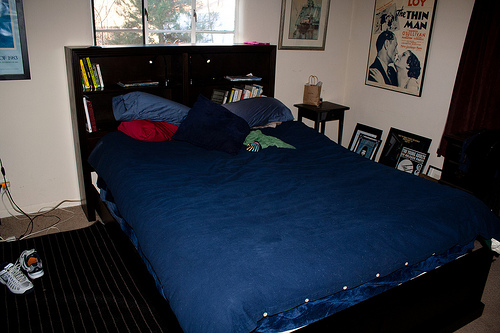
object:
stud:
[260, 310, 272, 320]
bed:
[103, 32, 498, 318]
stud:
[301, 294, 313, 308]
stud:
[339, 283, 352, 293]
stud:
[373, 268, 383, 281]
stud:
[399, 257, 416, 271]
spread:
[89, 106, 497, 312]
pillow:
[112, 120, 182, 141]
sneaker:
[0, 264, 36, 298]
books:
[113, 79, 162, 87]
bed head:
[58, 33, 285, 127]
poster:
[363, 0, 423, 97]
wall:
[281, 2, 453, 132]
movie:
[402, 9, 435, 32]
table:
[297, 99, 352, 143]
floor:
[38, 278, 150, 333]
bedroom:
[2, 4, 499, 332]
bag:
[303, 77, 323, 107]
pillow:
[110, 92, 191, 123]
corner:
[292, 103, 357, 126]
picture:
[277, 0, 326, 47]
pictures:
[0, 0, 31, 84]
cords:
[45, 196, 81, 211]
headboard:
[56, 37, 285, 99]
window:
[89, 2, 141, 33]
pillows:
[179, 103, 244, 154]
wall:
[22, 4, 280, 47]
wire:
[5, 178, 18, 212]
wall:
[0, 112, 72, 217]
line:
[132, 256, 145, 332]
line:
[79, 232, 84, 265]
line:
[88, 231, 100, 264]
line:
[94, 270, 113, 332]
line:
[29, 292, 45, 331]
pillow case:
[109, 89, 191, 122]